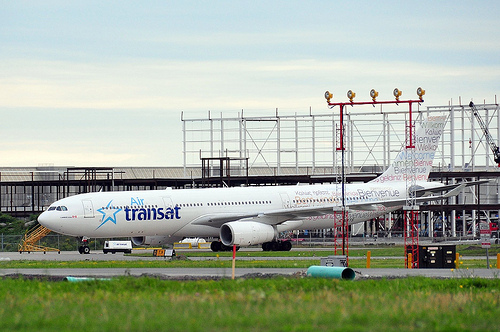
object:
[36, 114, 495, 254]
plane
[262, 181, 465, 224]
wing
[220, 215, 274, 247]
propeller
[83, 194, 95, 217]
door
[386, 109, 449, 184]
tail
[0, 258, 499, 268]
grass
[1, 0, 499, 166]
sky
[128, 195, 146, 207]
word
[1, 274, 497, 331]
grass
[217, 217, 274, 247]
engine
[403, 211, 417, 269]
metal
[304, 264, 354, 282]
pipe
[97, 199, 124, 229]
graphic